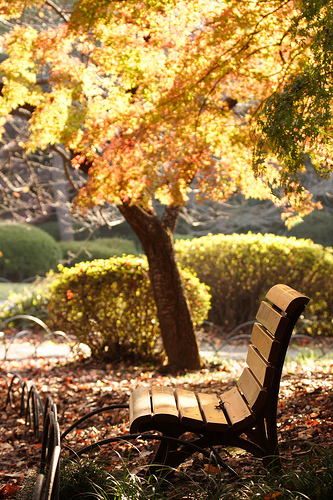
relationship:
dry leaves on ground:
[278, 360, 329, 450] [0, 231, 332, 497]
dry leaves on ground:
[0, 354, 133, 453] [0, 231, 332, 497]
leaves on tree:
[107, 75, 187, 149] [0, 0, 307, 372]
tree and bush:
[3, 35, 308, 373] [47, 252, 211, 361]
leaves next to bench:
[149, 112, 230, 391] [109, 281, 309, 397]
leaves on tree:
[0, 0, 332, 231] [0, 0, 307, 372]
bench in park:
[128, 283, 311, 477] [1, 0, 332, 498]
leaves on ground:
[2, 326, 332, 497] [0, 321, 330, 499]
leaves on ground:
[70, 372, 107, 395] [33, 334, 150, 402]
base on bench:
[142, 415, 285, 482] [128, 283, 311, 477]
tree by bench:
[0, 0, 307, 372] [128, 283, 311, 477]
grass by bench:
[53, 446, 331, 499] [128, 283, 311, 477]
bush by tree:
[47, 252, 214, 361] [0, 0, 307, 372]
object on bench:
[214, 398, 229, 412] [128, 283, 311, 477]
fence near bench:
[0, 369, 65, 499] [128, 283, 311, 477]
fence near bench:
[0, 369, 65, 499] [128, 282, 310, 499]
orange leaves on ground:
[60, 389, 103, 414] [78, 389, 113, 406]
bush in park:
[168, 229, 331, 336] [1, 0, 332, 498]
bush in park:
[47, 252, 214, 361] [1, 0, 332, 498]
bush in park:
[93, 234, 136, 253] [1, 0, 332, 498]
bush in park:
[57, 238, 117, 261] [1, 0, 332, 498]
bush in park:
[0, 221, 74, 279] [1, 0, 332, 498]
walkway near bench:
[195, 335, 331, 364] [128, 283, 311, 477]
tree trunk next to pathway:
[70, 149, 200, 370] [2, 334, 331, 373]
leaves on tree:
[3, 0, 303, 204] [11, 3, 267, 378]